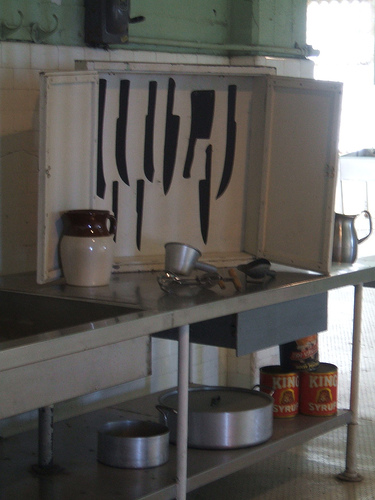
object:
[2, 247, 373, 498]
table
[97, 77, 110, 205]
knife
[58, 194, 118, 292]
jar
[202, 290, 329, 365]
drawer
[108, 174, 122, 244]
knife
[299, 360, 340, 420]
can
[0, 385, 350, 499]
shelf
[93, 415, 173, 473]
stock pot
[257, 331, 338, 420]
labels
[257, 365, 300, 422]
can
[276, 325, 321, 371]
can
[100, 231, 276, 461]
pot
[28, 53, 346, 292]
box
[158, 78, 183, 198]
knives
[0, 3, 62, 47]
hooks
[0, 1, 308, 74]
wall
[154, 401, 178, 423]
handle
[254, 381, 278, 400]
handle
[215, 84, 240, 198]
knife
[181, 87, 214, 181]
knife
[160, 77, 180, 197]
knife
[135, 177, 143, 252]
knife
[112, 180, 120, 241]
knife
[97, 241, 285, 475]
pan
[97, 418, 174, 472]
pan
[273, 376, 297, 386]
word king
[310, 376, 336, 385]
word king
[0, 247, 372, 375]
countertop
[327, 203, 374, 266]
metal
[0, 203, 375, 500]
metal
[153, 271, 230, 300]
metal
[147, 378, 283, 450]
metal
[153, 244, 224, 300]
metal beaters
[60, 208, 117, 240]
brown area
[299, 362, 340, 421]
canned goods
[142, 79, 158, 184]
knife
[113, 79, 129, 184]
knife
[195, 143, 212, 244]
knife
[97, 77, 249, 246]
case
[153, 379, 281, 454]
pot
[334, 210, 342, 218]
spout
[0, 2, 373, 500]
kitchen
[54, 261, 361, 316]
shelf